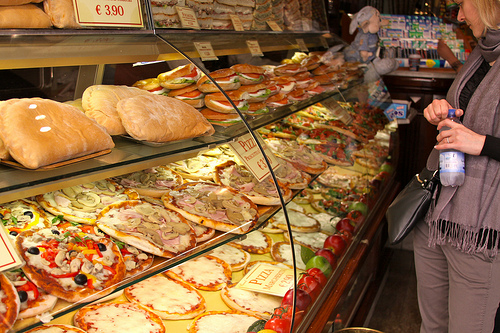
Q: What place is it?
A: It is a display.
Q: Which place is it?
A: It is a display.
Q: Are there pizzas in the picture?
A: Yes, there is a pizza.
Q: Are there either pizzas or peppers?
A: Yes, there is a pizza.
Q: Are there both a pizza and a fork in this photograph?
A: No, there is a pizza but no forks.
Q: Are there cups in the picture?
A: No, there are no cups.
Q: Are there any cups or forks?
A: No, there are no cups or forks.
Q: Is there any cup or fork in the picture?
A: No, there are no cups or forks.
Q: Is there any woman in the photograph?
A: Yes, there is a woman.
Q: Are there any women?
A: Yes, there is a woman.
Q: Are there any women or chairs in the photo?
A: Yes, there is a woman.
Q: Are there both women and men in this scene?
A: No, there is a woman but no men.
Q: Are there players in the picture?
A: No, there are no players.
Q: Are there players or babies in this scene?
A: No, there are no players or babies.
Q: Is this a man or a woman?
A: This is a woman.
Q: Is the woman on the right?
A: Yes, the woman is on the right of the image.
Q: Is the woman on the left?
A: No, the woman is on the right of the image.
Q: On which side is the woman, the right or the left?
A: The woman is on the right of the image.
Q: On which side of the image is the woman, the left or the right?
A: The woman is on the right of the image.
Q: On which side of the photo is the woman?
A: The woman is on the right of the image.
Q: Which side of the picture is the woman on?
A: The woman is on the right of the image.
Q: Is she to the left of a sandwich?
A: No, the woman is to the right of a sandwich.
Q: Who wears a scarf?
A: The woman wears a scarf.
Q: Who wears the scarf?
A: The woman wears a scarf.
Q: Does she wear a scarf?
A: Yes, the woman wears a scarf.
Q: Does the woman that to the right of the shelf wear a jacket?
A: No, the woman wears a scarf.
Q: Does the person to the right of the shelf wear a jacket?
A: No, the woman wears a scarf.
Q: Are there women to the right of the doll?
A: Yes, there is a woman to the right of the doll.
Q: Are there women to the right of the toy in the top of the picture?
A: Yes, there is a woman to the right of the doll.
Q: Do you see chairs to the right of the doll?
A: No, there is a woman to the right of the doll.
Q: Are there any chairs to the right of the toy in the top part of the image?
A: No, there is a woman to the right of the doll.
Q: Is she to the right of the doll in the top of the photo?
A: Yes, the woman is to the right of the doll.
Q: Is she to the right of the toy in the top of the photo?
A: Yes, the woman is to the right of the doll.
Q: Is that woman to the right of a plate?
A: No, the woman is to the right of the doll.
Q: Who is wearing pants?
A: The woman is wearing pants.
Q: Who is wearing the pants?
A: The woman is wearing pants.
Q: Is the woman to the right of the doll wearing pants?
A: Yes, the woman is wearing pants.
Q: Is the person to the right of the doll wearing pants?
A: Yes, the woman is wearing pants.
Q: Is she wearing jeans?
A: No, the woman is wearing pants.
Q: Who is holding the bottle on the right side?
A: The woman is holding the bottle.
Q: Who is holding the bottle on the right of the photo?
A: The woman is holding the bottle.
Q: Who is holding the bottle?
A: The woman is holding the bottle.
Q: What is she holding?
A: The woman is holding the bottle.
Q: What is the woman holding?
A: The woman is holding the bottle.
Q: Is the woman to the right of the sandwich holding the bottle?
A: Yes, the woman is holding the bottle.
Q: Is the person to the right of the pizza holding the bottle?
A: Yes, the woman is holding the bottle.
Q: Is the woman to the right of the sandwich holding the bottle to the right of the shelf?
A: Yes, the woman is holding the bottle.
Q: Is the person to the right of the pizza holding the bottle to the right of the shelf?
A: Yes, the woman is holding the bottle.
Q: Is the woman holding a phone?
A: No, the woman is holding the bottle.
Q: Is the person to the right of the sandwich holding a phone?
A: No, the woman is holding the bottle.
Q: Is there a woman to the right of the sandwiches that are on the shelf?
A: Yes, there is a woman to the right of the sandwiches.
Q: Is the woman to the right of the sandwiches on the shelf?
A: Yes, the woman is to the right of the sandwiches.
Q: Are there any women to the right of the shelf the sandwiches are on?
A: Yes, there is a woman to the right of the shelf.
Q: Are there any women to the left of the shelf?
A: No, the woman is to the right of the shelf.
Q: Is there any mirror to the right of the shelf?
A: No, there is a woman to the right of the shelf.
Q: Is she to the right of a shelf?
A: Yes, the woman is to the right of a shelf.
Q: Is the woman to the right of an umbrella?
A: No, the woman is to the right of a shelf.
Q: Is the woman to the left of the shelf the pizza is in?
A: No, the woman is to the right of the shelf.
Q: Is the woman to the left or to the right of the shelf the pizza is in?
A: The woman is to the right of the shelf.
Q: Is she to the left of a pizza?
A: No, the woman is to the right of a pizza.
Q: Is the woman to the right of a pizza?
A: Yes, the woman is to the right of a pizza.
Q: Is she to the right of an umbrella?
A: No, the woman is to the right of a pizza.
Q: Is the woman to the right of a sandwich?
A: Yes, the woman is to the right of a sandwich.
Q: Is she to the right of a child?
A: No, the woman is to the right of a sandwich.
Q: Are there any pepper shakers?
A: No, there are no pepper shakers.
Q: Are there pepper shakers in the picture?
A: No, there are no pepper shakers.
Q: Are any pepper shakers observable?
A: No, there are no pepper shakers.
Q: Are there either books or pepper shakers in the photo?
A: No, there are no pepper shakers or books.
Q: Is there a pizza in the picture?
A: Yes, there is a pizza.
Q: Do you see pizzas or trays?
A: Yes, there is a pizza.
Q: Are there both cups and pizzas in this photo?
A: No, there is a pizza but no cups.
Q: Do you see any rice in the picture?
A: No, there is no rice.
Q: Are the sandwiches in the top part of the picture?
A: Yes, the sandwiches are in the top of the image.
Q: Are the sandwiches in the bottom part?
A: No, the sandwiches are in the top of the image.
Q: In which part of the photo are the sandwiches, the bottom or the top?
A: The sandwiches are in the top of the image.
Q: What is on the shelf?
A: The sandwiches are on the shelf.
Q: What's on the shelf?
A: The sandwiches are on the shelf.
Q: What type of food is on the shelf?
A: The food is sandwiches.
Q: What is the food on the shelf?
A: The food is sandwiches.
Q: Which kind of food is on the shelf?
A: The food is sandwiches.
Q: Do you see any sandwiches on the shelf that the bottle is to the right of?
A: Yes, there are sandwiches on the shelf.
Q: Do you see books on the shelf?
A: No, there are sandwiches on the shelf.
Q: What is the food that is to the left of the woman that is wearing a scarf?
A: The food is sandwiches.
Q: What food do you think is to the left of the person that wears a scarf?
A: The food is sandwiches.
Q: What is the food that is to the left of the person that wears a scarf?
A: The food is sandwiches.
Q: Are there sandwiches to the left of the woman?
A: Yes, there are sandwiches to the left of the woman.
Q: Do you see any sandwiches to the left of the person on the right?
A: Yes, there are sandwiches to the left of the woman.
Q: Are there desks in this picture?
A: No, there are no desks.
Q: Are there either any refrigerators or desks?
A: No, there are no desks or refrigerators.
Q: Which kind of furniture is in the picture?
A: The furniture is a shelf.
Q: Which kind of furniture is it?
A: The piece of furniture is a shelf.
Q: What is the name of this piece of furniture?
A: This is a shelf.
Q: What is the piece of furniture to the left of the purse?
A: The piece of furniture is a shelf.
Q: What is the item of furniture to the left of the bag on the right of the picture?
A: The piece of furniture is a shelf.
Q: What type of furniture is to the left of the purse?
A: The piece of furniture is a shelf.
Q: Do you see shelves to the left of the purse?
A: Yes, there is a shelf to the left of the purse.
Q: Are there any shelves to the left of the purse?
A: Yes, there is a shelf to the left of the purse.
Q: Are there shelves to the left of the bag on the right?
A: Yes, there is a shelf to the left of the purse.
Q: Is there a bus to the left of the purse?
A: No, there is a shelf to the left of the purse.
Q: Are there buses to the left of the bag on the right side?
A: No, there is a shelf to the left of the purse.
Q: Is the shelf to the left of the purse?
A: Yes, the shelf is to the left of the purse.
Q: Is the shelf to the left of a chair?
A: No, the shelf is to the left of the purse.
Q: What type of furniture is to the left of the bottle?
A: The piece of furniture is a shelf.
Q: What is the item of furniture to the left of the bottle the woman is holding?
A: The piece of furniture is a shelf.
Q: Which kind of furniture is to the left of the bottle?
A: The piece of furniture is a shelf.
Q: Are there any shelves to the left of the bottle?
A: Yes, there is a shelf to the left of the bottle.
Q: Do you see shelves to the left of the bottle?
A: Yes, there is a shelf to the left of the bottle.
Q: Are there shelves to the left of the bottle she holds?
A: Yes, there is a shelf to the left of the bottle.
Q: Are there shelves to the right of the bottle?
A: No, the shelf is to the left of the bottle.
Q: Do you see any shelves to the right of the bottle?
A: No, the shelf is to the left of the bottle.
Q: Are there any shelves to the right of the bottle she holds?
A: No, the shelf is to the left of the bottle.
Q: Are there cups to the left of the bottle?
A: No, there is a shelf to the left of the bottle.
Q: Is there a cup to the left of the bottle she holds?
A: No, there is a shelf to the left of the bottle.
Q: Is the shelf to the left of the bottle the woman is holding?
A: Yes, the shelf is to the left of the bottle.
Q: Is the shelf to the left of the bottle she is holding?
A: Yes, the shelf is to the left of the bottle.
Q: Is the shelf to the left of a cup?
A: No, the shelf is to the left of the bottle.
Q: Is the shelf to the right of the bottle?
A: No, the shelf is to the left of the bottle.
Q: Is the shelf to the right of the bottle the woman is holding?
A: No, the shelf is to the left of the bottle.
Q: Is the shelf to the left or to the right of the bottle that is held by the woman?
A: The shelf is to the left of the bottle.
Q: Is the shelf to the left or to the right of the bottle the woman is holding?
A: The shelf is to the left of the bottle.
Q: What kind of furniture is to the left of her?
A: The piece of furniture is a shelf.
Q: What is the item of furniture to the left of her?
A: The piece of furniture is a shelf.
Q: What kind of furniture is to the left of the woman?
A: The piece of furniture is a shelf.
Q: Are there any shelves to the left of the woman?
A: Yes, there is a shelf to the left of the woman.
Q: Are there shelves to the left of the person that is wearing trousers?
A: Yes, there is a shelf to the left of the woman.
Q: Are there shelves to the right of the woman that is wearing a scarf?
A: No, the shelf is to the left of the woman.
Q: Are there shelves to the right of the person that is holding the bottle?
A: No, the shelf is to the left of the woman.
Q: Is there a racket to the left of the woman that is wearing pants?
A: No, there is a shelf to the left of the woman.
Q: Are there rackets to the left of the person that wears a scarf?
A: No, there is a shelf to the left of the woman.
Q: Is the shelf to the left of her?
A: Yes, the shelf is to the left of a woman.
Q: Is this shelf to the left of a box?
A: No, the shelf is to the left of a woman.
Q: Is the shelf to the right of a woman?
A: No, the shelf is to the left of a woman.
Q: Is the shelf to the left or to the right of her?
A: The shelf is to the left of the woman.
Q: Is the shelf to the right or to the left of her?
A: The shelf is to the left of the woman.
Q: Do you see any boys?
A: No, there are no boys.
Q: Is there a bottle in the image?
A: Yes, there is a bottle.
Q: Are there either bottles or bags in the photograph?
A: Yes, there is a bottle.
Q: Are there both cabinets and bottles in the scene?
A: No, there is a bottle but no cabinets.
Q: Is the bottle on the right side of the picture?
A: Yes, the bottle is on the right of the image.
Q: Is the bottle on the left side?
A: No, the bottle is on the right of the image.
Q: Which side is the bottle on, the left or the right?
A: The bottle is on the right of the image.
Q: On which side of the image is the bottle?
A: The bottle is on the right of the image.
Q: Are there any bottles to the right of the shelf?
A: Yes, there is a bottle to the right of the shelf.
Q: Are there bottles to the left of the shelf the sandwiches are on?
A: No, the bottle is to the right of the shelf.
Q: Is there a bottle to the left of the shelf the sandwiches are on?
A: No, the bottle is to the right of the shelf.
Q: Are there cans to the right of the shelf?
A: No, there is a bottle to the right of the shelf.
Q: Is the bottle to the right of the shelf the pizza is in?
A: Yes, the bottle is to the right of the shelf.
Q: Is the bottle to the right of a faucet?
A: No, the bottle is to the right of the shelf.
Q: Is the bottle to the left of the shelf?
A: No, the bottle is to the right of the shelf.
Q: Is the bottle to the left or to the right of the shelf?
A: The bottle is to the right of the shelf.